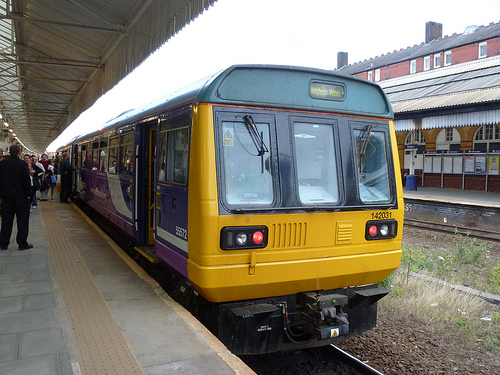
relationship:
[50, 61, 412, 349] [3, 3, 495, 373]
train in station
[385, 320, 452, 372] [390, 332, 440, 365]
gravel on ground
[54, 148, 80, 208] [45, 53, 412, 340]
man to board bus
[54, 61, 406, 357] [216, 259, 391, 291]
train with bumper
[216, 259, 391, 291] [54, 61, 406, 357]
bumper on train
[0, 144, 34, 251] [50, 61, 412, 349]
man waiting for train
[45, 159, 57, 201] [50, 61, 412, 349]
person waiting for train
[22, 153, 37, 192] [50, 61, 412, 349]
person waiting for train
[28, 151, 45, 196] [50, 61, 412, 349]
person waiting for train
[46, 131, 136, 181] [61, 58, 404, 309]
windows on train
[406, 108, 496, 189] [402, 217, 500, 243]
store next to tracks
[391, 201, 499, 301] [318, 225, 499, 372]
tracks on ground